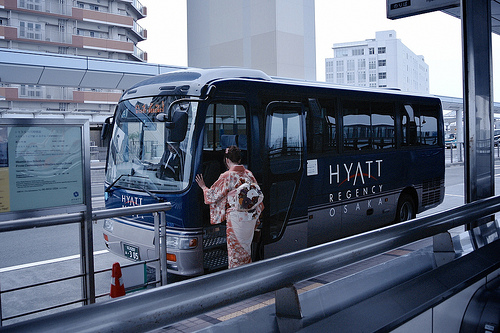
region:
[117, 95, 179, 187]
windshield on the bus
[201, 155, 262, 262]
woman entering the bus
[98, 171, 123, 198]
windshield wiper on window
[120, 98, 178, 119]
destination of the bus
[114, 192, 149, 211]
hyatt printed on front of bus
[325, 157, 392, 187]
hyatt written on side of bus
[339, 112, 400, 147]
window on side of bus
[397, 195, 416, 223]
tire on back of bus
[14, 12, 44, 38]
window on the building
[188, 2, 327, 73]
building behind the bus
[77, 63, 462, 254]
bus for passengers to travel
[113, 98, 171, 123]
bus route and info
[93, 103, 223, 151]
mirrors on the bus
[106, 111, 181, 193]
window on front of bus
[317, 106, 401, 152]
windows on the bus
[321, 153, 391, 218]
brand on the bus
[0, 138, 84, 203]
information on the stand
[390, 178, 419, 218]
tire on the bus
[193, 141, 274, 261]
woman boarding the bus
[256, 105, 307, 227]
door to the vehicle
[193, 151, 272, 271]
Geisha at the bus window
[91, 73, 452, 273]
shuttle bus for a hotel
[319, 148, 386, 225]
Hyatt Regency Osaka on the bus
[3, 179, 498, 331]
metal guard rail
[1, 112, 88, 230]
informational signs under the glass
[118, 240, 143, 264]
front license plate on the bus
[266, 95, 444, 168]
side windows of the bus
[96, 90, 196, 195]
large front windshield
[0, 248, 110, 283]
white line on the road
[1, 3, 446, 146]
several buildings next to the road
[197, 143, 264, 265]
woman entering into bus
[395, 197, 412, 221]
rear wheel of bus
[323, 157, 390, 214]
white writing on bus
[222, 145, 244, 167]
black hair of lady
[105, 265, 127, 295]
orange cone by bus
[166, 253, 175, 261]
orange light on bus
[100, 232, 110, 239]
orange light of bus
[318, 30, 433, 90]
building above parked bus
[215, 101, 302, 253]
opened door of bus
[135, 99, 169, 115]
digital sign on bus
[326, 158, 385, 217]
hotel logo on side of bus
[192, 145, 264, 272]
woman boarding a bus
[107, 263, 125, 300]
orange traffic cone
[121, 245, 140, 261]
license plate on front of bus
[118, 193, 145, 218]
hotel logo on front of bus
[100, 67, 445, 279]
blue and grey van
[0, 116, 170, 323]
metal and glass dividing wall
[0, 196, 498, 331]
metal handrail on top of wall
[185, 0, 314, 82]
multi-storied building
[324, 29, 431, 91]
white multi-storied building